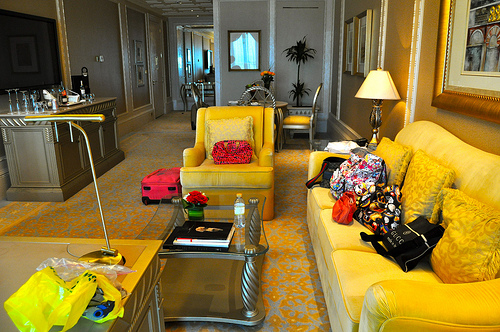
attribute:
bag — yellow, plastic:
[2, 260, 129, 331]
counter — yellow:
[1, 231, 165, 331]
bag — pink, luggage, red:
[137, 164, 182, 208]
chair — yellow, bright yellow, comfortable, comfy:
[177, 99, 281, 223]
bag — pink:
[211, 137, 252, 168]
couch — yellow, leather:
[303, 117, 500, 331]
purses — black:
[360, 210, 450, 274]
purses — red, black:
[304, 153, 351, 195]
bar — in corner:
[1, 89, 126, 206]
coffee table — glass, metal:
[133, 193, 272, 331]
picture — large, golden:
[429, 1, 500, 128]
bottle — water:
[232, 190, 246, 229]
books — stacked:
[159, 218, 240, 255]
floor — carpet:
[1, 108, 471, 331]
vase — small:
[262, 80, 274, 101]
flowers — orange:
[259, 67, 278, 82]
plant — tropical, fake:
[279, 37, 324, 144]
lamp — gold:
[352, 67, 405, 158]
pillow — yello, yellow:
[362, 136, 411, 202]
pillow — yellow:
[395, 147, 457, 245]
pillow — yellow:
[430, 186, 499, 288]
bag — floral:
[327, 151, 388, 205]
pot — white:
[285, 102, 322, 143]